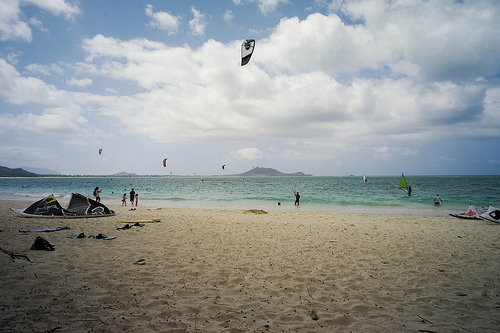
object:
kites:
[99, 146, 230, 171]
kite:
[239, 35, 256, 67]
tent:
[14, 191, 116, 219]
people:
[89, 185, 141, 206]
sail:
[395, 169, 411, 189]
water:
[0, 174, 500, 222]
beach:
[2, 197, 500, 330]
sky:
[1, 1, 500, 174]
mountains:
[232, 166, 320, 179]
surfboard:
[14, 222, 70, 235]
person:
[430, 194, 441, 205]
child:
[132, 192, 140, 205]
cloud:
[256, 10, 385, 71]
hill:
[107, 169, 142, 177]